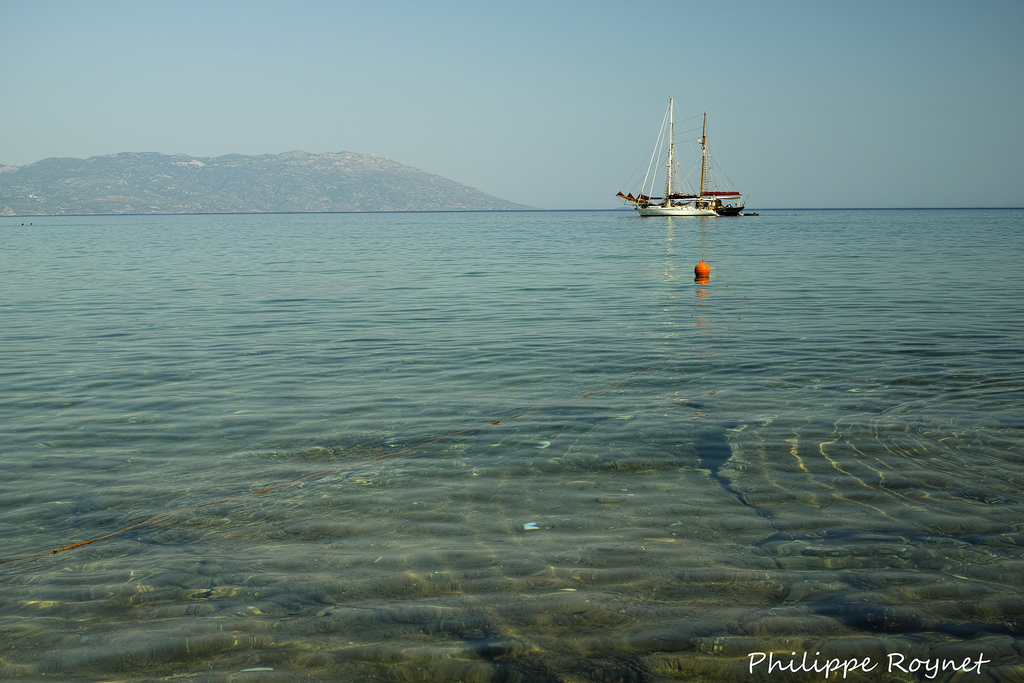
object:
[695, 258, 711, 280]
buoy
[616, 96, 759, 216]
boat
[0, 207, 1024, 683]
water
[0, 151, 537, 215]
hill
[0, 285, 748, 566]
stick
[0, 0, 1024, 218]
sky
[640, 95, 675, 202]
mast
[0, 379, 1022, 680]
ripples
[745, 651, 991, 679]
signature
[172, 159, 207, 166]
house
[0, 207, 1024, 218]
horizon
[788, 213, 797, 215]
swimmers